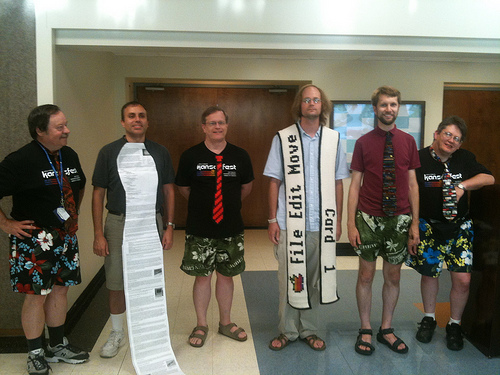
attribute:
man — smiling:
[175, 103, 260, 364]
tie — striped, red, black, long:
[212, 151, 240, 223]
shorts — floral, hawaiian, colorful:
[417, 231, 488, 276]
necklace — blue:
[40, 148, 72, 198]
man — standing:
[27, 95, 89, 216]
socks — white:
[105, 305, 128, 331]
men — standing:
[16, 101, 476, 319]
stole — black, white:
[283, 135, 320, 296]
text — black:
[287, 164, 307, 253]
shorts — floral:
[11, 229, 90, 295]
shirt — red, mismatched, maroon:
[358, 130, 417, 205]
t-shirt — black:
[179, 149, 263, 237]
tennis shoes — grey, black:
[12, 344, 85, 375]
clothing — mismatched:
[357, 140, 411, 261]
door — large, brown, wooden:
[166, 93, 284, 187]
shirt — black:
[410, 148, 500, 217]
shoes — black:
[411, 316, 466, 352]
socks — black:
[18, 329, 72, 349]